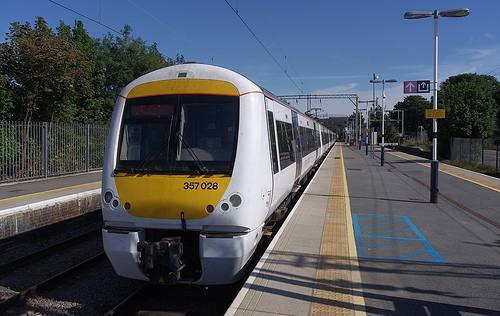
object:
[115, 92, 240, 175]
windows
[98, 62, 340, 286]
bus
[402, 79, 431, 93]
sign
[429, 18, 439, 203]
light post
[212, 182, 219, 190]
numbers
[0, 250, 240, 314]
tracks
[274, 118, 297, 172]
small windows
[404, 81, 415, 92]
arrow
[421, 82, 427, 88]
arrow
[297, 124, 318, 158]
windows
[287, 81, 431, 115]
cloud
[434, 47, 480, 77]
cloud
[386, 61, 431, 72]
cloud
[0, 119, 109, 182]
fence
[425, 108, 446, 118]
sign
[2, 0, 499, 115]
sky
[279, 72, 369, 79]
cloud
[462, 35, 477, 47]
cloud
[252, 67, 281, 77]
cloud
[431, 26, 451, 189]
pole